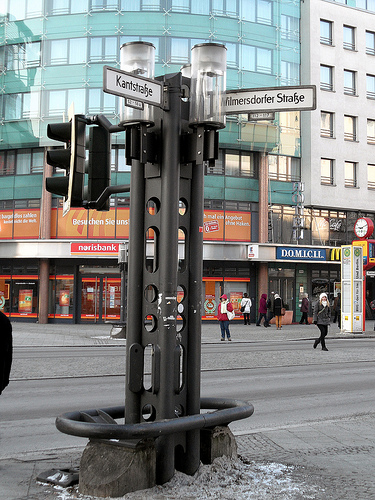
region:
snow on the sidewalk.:
[207, 461, 242, 489]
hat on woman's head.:
[318, 292, 327, 296]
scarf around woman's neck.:
[320, 300, 328, 308]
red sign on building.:
[68, 245, 115, 251]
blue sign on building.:
[278, 249, 320, 255]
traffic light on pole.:
[46, 117, 79, 198]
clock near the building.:
[350, 218, 370, 239]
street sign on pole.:
[99, 81, 160, 97]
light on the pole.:
[190, 62, 218, 124]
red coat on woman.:
[218, 314, 221, 317]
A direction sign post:
[100, 67, 169, 116]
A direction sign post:
[226, 88, 317, 125]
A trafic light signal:
[26, 110, 111, 208]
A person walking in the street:
[308, 295, 339, 353]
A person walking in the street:
[216, 286, 240, 339]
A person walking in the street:
[237, 289, 254, 326]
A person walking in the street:
[257, 286, 267, 328]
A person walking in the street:
[273, 288, 285, 336]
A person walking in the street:
[293, 287, 306, 334]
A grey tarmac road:
[267, 349, 361, 464]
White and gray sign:
[221, 85, 316, 113]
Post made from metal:
[159, 72, 174, 479]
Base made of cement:
[77, 424, 235, 497]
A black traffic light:
[46, 114, 109, 210]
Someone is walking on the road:
[312, 293, 330, 349]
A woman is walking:
[217, 293, 234, 342]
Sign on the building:
[71, 241, 118, 254]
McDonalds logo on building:
[330, 247, 340, 260]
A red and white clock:
[354, 216, 372, 237]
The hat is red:
[219, 293, 227, 298]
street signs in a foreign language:
[93, 66, 318, 121]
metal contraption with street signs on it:
[70, 45, 262, 475]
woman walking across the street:
[308, 294, 338, 352]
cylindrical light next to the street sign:
[187, 40, 229, 131]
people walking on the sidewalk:
[241, 293, 310, 329]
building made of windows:
[6, 2, 308, 210]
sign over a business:
[272, 243, 345, 262]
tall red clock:
[353, 216, 372, 249]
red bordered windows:
[2, 270, 122, 325]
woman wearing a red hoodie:
[216, 293, 235, 341]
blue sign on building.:
[274, 250, 324, 259]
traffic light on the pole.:
[53, 121, 72, 198]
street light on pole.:
[194, 54, 224, 119]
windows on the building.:
[231, 155, 249, 166]